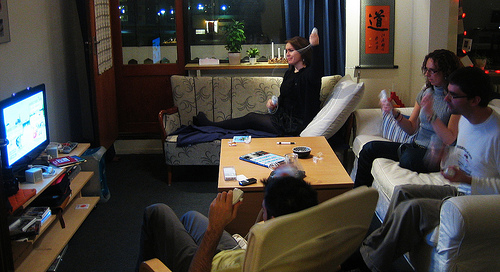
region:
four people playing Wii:
[123, 25, 498, 224]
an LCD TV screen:
[0, 80, 51, 185]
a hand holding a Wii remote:
[206, 183, 247, 228]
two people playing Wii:
[380, 48, 488, 178]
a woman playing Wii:
[264, 27, 321, 127]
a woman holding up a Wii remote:
[281, 26, 326, 82]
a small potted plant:
[221, 13, 247, 64]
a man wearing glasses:
[436, 64, 493, 123]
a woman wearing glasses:
[417, 46, 454, 90]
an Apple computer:
[77, 143, 109, 206]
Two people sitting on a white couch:
[352, 46, 499, 270]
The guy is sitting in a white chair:
[136, 172, 378, 270]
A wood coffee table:
[214, 133, 357, 228]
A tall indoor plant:
[223, 18, 245, 65]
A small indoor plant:
[244, 45, 259, 62]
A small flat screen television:
[3, 80, 51, 175]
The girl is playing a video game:
[187, 28, 327, 135]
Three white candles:
[268, 40, 287, 62]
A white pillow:
[300, 75, 365, 138]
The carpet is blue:
[62, 145, 221, 270]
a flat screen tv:
[0, 74, 58, 179]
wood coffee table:
[204, 127, 351, 212]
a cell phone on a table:
[220, 174, 260, 196]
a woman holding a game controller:
[266, 14, 351, 121]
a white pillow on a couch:
[293, 69, 363, 148]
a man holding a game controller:
[411, 71, 484, 207]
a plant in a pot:
[223, 21, 243, 64]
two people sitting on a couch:
[362, 42, 483, 208]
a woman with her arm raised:
[283, 14, 322, 96]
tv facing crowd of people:
[3, 88, 50, 169]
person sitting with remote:
[140, 179, 320, 269]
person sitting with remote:
[354, 48, 466, 187]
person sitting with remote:
[358, 77, 496, 262]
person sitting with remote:
[195, 28, 340, 130]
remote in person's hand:
[230, 183, 245, 203]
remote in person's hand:
[442, 170, 456, 176]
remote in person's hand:
[378, 88, 390, 106]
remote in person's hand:
[308, 29, 320, 40]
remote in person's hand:
[263, 98, 277, 109]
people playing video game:
[5, 13, 494, 260]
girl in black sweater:
[168, 24, 348, 160]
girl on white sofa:
[151, 34, 349, 145]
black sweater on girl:
[270, 60, 308, 134]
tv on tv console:
[1, 82, 58, 167]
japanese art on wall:
[358, 5, 400, 69]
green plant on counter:
[222, 22, 247, 62]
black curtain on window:
[281, 4, 342, 76]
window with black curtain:
[108, 3, 335, 64]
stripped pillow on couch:
[385, 107, 410, 137]